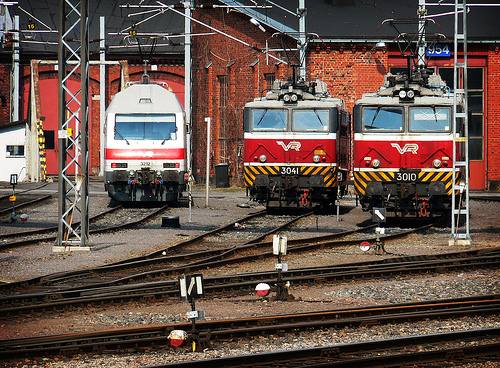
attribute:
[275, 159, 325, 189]
number — white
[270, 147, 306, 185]
number — white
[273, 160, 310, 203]
number — white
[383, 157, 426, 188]
number — white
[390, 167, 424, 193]
number — white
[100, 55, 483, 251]
trains — parked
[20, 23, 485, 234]
yard — rail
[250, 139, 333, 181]
lights — head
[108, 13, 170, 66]
wires — electric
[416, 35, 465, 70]
numbers — 954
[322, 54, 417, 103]
wall — brick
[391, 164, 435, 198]
number — 3010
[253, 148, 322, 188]
number — 3041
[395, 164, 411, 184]
white number — white 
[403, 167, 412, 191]
white number — white 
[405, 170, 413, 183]
white number — white 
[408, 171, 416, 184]
white number — white 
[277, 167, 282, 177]
white number — white 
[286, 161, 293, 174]
white number — white 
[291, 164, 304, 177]
white number — white 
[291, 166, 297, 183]
white number — white 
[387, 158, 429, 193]
white numbers — white 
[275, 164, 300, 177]
white numbers — white 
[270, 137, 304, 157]
white letters — white 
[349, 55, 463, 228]
train car — yellow 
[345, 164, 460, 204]
stripes — black 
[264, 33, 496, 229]
brick building — red  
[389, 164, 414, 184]
white numbers — white 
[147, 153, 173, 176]
black numbers — black 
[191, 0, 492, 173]
brick building — red 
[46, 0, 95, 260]
metal post — grey , metal  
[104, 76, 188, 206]
train — red , white 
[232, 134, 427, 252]
trains —  red and white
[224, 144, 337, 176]
frame — yellow , black 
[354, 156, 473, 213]
frame — black , yellow 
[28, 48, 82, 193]
door — red 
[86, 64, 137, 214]
door — red 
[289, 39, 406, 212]
door — red 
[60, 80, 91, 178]
numbers — white 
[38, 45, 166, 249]
door — red 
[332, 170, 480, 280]
trolley — white , Red 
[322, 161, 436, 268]
trolley — Red , white 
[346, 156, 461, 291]
trolley — white , Red 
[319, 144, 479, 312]
trolley — Red , white 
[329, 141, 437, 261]
trolley — white , Red 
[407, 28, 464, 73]
sign — blue 